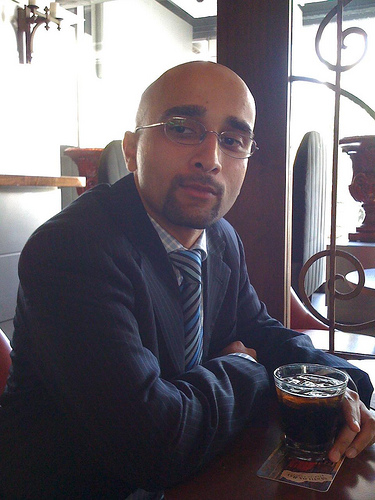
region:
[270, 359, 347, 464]
dark liquod drink in a glass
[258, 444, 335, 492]
coaster that drink is on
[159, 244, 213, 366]
striped tie on man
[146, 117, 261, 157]
glasses that is on the man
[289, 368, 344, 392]
ice cubes in the drink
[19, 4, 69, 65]
white candle on the wall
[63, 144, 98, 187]
red vase in back of the man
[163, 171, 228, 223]
goatee on the man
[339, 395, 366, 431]
finger pointing on the man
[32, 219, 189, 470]
part of a suit jacket of the man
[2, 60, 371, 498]
a business man sitting inside of a bar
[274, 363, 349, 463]
an alcoholic beverage on a coaster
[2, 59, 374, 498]
a bald man in a blue suit and tie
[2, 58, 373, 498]
a business man having a drink during happy hour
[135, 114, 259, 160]
eyeglasses on the man's eyes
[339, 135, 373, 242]
a vase artifact on the table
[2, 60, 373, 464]
a man grasping a glass beverage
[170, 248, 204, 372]
a blue stripped neck tie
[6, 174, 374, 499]
a male blue strip suit jacket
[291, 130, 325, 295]
the back of a black chair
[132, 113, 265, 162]
a pair of wire rimmed glasses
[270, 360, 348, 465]
a dark beverage in a glass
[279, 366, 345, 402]
a few ice cubes in a beverage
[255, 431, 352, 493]
a colorful coaster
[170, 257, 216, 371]
a blue and grey striped towel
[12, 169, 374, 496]
a pinstriped blue jacket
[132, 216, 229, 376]
a blue checkered button up shirt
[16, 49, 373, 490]
a man wearing a suit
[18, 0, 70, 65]
a wooden candle holder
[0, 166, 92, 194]
a rustic wood shelf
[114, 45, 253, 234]
man is bald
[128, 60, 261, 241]
man has facial hair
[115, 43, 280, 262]
man wearing oval metal framed glasses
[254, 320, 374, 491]
dark drink with ice cube in it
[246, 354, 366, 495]
glass sitting on coaster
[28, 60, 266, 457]
man wearing striped tie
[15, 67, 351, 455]
man wearing suit jacket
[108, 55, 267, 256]
man with thick eyebrow and dark eyes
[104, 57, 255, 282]
man wearing checkered shirt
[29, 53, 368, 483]
man sitting down at table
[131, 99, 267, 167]
Man is wearing eyeglasses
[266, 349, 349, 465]
Man is holding a drink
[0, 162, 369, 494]
Man is wearing a suit and tie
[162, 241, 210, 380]
Man's tie is striped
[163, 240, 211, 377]
Man's tie is blue, gray and black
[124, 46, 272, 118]
The man is bald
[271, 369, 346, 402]
Ice cubes in the drink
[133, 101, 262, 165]
Mans eyeglasses have a wire frame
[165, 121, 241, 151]
Man has brown colored eyes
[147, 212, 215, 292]
Man is wearing a light blue dress shirt